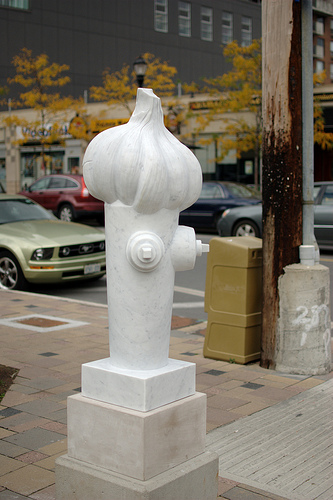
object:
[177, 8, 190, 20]
window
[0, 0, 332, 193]
building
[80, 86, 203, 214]
top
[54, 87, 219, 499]
hydrant